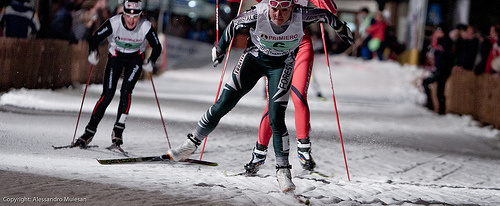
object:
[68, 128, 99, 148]
boot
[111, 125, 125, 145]
boot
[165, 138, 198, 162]
boot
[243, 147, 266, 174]
boot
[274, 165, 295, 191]
boot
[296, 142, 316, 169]
boot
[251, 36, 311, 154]
pants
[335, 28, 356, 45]
glove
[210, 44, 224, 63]
glove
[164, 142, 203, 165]
ski boot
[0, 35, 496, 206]
ground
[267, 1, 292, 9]
goggles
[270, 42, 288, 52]
number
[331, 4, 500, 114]
crowd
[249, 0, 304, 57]
vest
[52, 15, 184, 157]
outfit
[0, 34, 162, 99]
wooden fence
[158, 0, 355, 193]
man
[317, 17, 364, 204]
ski pole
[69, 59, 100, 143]
ski pole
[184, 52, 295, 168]
pants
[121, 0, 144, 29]
head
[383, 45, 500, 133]
fence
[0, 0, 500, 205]
ski race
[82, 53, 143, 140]
pants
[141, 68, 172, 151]
ski pole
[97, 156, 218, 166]
ski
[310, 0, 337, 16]
flag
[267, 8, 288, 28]
person's face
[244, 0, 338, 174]
man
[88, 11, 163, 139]
uniform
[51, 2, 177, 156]
athlete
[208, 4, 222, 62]
pole